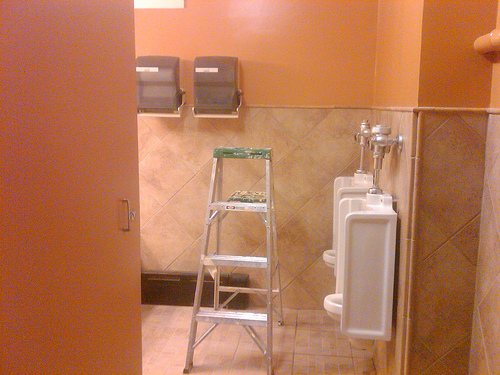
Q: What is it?
A: Restroom.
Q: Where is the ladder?
A: In the restroom.